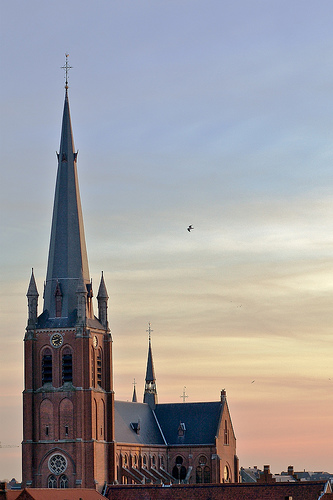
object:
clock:
[49, 332, 64, 348]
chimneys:
[255, 466, 305, 484]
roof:
[116, 401, 224, 445]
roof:
[108, 485, 333, 499]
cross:
[146, 322, 152, 341]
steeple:
[143, 341, 158, 403]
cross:
[60, 51, 74, 85]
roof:
[25, 87, 110, 332]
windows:
[39, 395, 74, 443]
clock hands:
[53, 339, 61, 344]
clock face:
[52, 333, 62, 347]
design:
[54, 282, 64, 317]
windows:
[38, 341, 74, 386]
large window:
[47, 452, 68, 475]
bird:
[186, 221, 195, 233]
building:
[0, 52, 333, 499]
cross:
[178, 386, 190, 404]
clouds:
[1, 1, 333, 482]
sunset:
[160, 270, 309, 378]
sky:
[0, 1, 333, 484]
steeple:
[23, 53, 106, 323]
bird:
[186, 222, 195, 232]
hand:
[56, 335, 59, 342]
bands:
[0, 351, 333, 500]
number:
[51, 335, 61, 347]